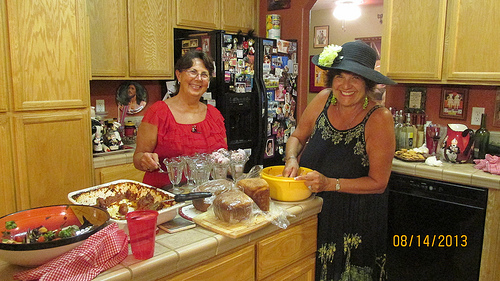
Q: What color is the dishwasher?
A: Black.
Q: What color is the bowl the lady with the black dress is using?
A: Yellow.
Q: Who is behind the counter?
A: The woman in the red shirt.